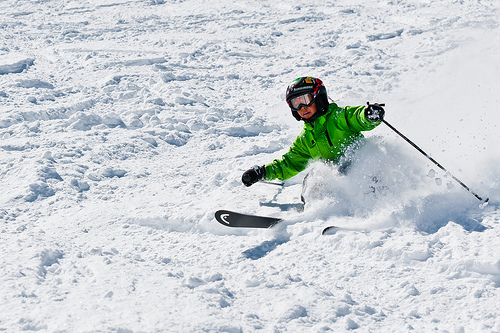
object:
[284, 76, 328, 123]
helmet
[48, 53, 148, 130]
snow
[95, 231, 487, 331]
snow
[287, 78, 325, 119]
head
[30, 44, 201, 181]
snow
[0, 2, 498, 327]
snow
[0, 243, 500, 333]
ground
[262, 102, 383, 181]
jacket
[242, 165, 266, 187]
glove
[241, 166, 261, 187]
hand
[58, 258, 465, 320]
snow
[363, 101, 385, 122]
glove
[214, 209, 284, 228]
ski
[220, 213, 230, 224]
symbol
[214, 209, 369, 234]
skis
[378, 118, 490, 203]
poles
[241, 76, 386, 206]
him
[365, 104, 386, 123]
hand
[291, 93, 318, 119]
face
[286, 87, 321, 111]
glasses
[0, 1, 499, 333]
hill